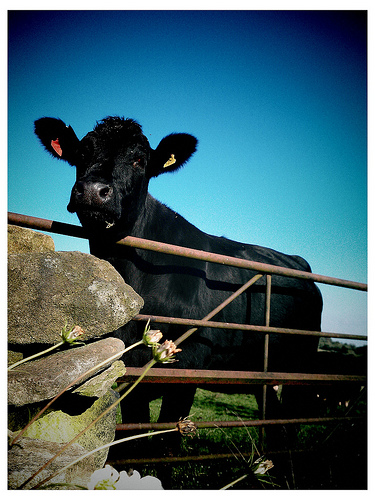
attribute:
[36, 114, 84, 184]
tag — red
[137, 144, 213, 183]
tag — yellow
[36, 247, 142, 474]
boulders — piled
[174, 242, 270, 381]
gate — iron, metal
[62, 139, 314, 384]
cow — curious, looking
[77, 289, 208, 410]
flowers — facing, close, leaning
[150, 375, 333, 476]
pasture — green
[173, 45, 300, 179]
sky — bright, blue, without, here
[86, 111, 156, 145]
fur — black, fluffy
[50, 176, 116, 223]
nose — shiny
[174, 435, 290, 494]
flower — lowest, pink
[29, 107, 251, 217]
ears — black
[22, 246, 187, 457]
rocks — stacked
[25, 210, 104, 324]
fence — rusty, brown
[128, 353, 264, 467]
grass — green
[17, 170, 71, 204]
fly — flying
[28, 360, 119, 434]
rock — gray, white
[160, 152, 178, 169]
tag — yellow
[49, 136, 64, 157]
tag — red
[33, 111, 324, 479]
cow — black